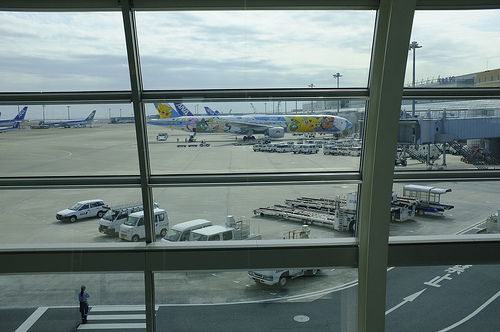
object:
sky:
[0, 7, 498, 122]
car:
[188, 225, 237, 243]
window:
[0, 1, 500, 332]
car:
[119, 209, 169, 243]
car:
[98, 200, 161, 236]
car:
[56, 199, 109, 223]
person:
[77, 285, 90, 322]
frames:
[0, 86, 500, 105]